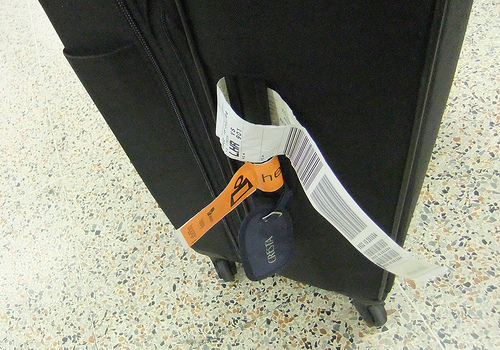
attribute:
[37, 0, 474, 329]
luggage — standing upright, black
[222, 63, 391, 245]
tag — white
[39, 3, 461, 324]
fabric luggage — black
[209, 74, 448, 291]
label — white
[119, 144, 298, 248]
tag — orange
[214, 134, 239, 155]
code — of destination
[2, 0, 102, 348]
lines — grout 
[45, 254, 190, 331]
floor —  colorful 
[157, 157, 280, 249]
yellow tag — yellow 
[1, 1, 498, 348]
tile floor —   tile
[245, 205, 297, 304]
tag — black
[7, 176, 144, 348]
flooring — multicolor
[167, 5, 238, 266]
zipper — in area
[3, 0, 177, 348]
floor —  of granite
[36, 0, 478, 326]
suitcase — black 